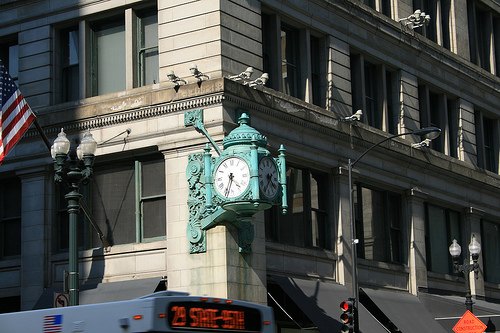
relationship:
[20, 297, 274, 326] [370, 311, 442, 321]
bus on street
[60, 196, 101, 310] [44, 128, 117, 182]
post of light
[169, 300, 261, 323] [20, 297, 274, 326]
word on bus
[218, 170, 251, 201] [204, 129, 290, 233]
face of clock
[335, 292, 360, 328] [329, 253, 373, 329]
light sharing pole